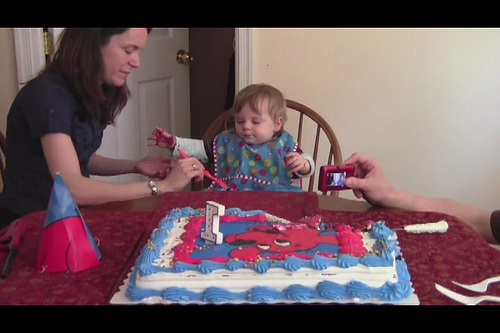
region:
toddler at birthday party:
[143, 82, 314, 192]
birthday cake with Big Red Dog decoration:
[133, 201, 428, 320]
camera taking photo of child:
[317, 159, 360, 194]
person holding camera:
[319, 147, 499, 255]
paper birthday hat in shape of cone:
[36, 170, 101, 275]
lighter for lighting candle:
[5, 215, 29, 287]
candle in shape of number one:
[196, 195, 227, 248]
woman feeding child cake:
[6, 24, 235, 206]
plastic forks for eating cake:
[433, 264, 498, 305]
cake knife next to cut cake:
[354, 215, 451, 239]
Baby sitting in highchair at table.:
[154, 83, 341, 193]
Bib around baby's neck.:
[208, 131, 304, 193]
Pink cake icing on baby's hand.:
[143, 121, 180, 156]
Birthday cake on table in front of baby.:
[114, 201, 422, 311]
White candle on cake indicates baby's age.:
[191, 191, 232, 248]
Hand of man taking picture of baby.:
[314, 151, 386, 204]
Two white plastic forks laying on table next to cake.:
[426, 252, 498, 305]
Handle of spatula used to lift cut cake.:
[388, 214, 453, 241]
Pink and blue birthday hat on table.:
[26, 166, 126, 282]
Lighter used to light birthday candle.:
[3, 209, 30, 291]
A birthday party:
[159, 71, 335, 221]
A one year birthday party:
[180, 183, 305, 254]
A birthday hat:
[8, 149, 195, 290]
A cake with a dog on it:
[216, 226, 393, 274]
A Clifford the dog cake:
[163, 206, 419, 307]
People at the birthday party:
[51, 82, 450, 329]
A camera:
[299, 136, 380, 218]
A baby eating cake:
[130, 88, 421, 246]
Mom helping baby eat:
[11, 124, 178, 196]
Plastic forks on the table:
[442, 215, 494, 308]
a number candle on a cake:
[182, 192, 227, 245]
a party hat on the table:
[31, 170, 99, 277]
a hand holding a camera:
[292, 144, 378, 207]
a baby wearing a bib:
[208, 90, 300, 188]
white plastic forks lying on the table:
[439, 263, 499, 305]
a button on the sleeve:
[44, 106, 59, 117]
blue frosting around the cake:
[201, 279, 284, 301]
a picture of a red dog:
[229, 218, 311, 254]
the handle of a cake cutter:
[394, 216, 452, 234]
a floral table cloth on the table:
[115, 216, 145, 234]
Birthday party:
[146, 177, 321, 324]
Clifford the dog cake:
[199, 185, 444, 312]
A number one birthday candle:
[176, 204, 271, 256]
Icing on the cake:
[146, 235, 270, 317]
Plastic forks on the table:
[410, 236, 482, 303]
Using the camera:
[309, 146, 443, 263]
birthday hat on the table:
[32, 177, 138, 307]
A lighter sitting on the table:
[0, 210, 34, 285]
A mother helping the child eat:
[157, 127, 283, 239]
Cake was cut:
[186, 161, 405, 248]